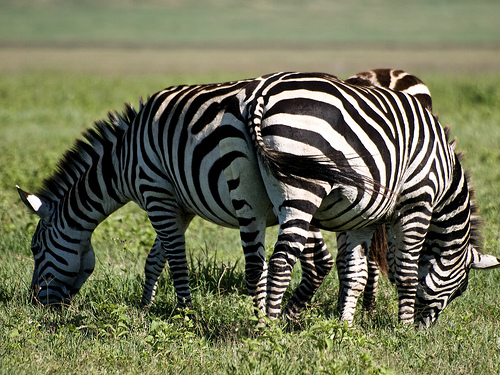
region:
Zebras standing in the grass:
[14, 71, 497, 327]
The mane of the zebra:
[39, 101, 133, 204]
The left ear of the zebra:
[18, 178, 43, 220]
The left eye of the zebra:
[29, 238, 44, 256]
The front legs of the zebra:
[140, 204, 192, 303]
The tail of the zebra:
[250, 88, 344, 185]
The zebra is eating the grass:
[259, 71, 497, 334]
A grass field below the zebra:
[8, 73, 495, 374]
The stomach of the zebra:
[181, 183, 236, 229]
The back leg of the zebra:
[264, 214, 318, 324]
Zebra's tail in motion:
[245, 93, 407, 207]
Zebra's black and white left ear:
[9, 179, 50, 216]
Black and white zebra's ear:
[463, 243, 498, 271]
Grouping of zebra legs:
[121, 219, 426, 339]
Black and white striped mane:
[42, 98, 144, 203]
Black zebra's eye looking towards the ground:
[25, 242, 45, 256]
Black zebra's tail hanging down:
[363, 217, 394, 277]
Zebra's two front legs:
[127, 203, 200, 314]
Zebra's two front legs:
[337, 208, 430, 330]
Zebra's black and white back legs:
[222, 160, 333, 348]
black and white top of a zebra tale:
[251, 95, 270, 156]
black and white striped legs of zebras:
[134, 263, 422, 331]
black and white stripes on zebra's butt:
[272, 70, 340, 184]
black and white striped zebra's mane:
[32, 111, 117, 177]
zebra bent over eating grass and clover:
[11, 181, 108, 318]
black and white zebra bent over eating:
[256, 70, 489, 340]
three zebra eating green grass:
[5, 60, 498, 352]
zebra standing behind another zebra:
[337, 63, 443, 128]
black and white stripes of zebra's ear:
[470, 238, 499, 272]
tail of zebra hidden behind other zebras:
[368, 215, 393, 272]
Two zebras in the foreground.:
[7, 69, 497, 333]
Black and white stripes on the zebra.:
[250, 68, 496, 340]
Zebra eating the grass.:
[20, 73, 267, 323]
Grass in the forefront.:
[2, 68, 497, 374]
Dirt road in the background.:
[0, 42, 498, 68]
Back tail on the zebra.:
[264, 134, 391, 206]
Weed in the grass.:
[162, 293, 198, 348]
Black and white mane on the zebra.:
[32, 93, 155, 220]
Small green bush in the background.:
[458, 78, 498, 115]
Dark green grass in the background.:
[2, 2, 498, 42]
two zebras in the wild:
[13, 65, 498, 328]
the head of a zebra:
[9, 183, 98, 315]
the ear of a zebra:
[8, 182, 47, 214]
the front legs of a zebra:
[141, 203, 198, 311]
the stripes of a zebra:
[129, 123, 247, 195]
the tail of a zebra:
[246, 94, 391, 194]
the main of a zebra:
[40, 102, 137, 202]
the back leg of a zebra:
[267, 210, 297, 345]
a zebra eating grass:
[10, 129, 140, 335]